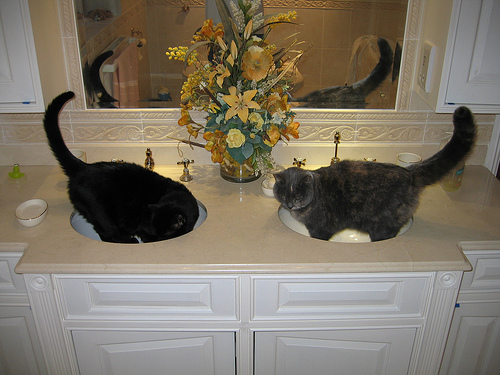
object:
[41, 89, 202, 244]
cats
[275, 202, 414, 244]
sink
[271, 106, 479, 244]
cat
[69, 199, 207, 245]
sinks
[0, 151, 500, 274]
counter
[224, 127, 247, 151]
flowers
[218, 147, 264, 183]
vase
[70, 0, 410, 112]
mirror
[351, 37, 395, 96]
tails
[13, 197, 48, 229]
bowl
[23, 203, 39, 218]
soap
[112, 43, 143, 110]
towel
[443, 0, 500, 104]
cabinet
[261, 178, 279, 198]
cup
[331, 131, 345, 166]
faucet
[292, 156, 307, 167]
handle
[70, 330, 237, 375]
cabinet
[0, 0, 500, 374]
bathroom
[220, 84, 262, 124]
lily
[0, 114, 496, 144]
trim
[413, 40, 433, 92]
outlet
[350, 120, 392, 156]
wall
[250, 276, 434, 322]
drawer